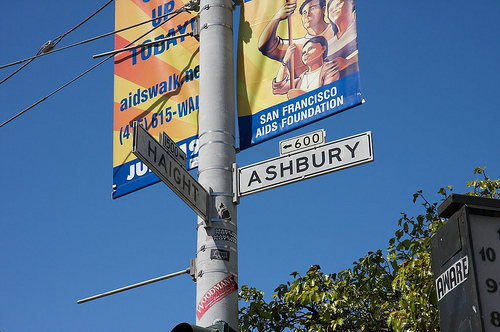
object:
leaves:
[322, 271, 359, 308]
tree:
[235, 169, 438, 332]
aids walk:
[107, 0, 361, 195]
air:
[4, 4, 114, 205]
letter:
[246, 169, 261, 185]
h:
[278, 159, 293, 177]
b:
[294, 155, 310, 173]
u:
[312, 151, 325, 168]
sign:
[312, 151, 326, 168]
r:
[327, 146, 342, 162]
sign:
[328, 147, 344, 164]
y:
[342, 138, 362, 158]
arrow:
[283, 143, 292, 149]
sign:
[230, 121, 377, 193]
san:
[258, 108, 279, 124]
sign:
[99, 1, 371, 204]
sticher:
[193, 270, 245, 322]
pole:
[188, 1, 244, 332]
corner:
[417, 183, 499, 330]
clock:
[468, 204, 500, 331]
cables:
[1, 2, 200, 131]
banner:
[102, 1, 369, 210]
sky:
[5, 0, 492, 233]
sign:
[128, 117, 215, 217]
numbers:
[161, 131, 180, 158]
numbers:
[293, 132, 319, 149]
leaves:
[392, 279, 431, 312]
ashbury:
[238, 130, 371, 194]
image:
[261, 0, 355, 100]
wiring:
[4, 3, 193, 137]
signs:
[234, 129, 375, 198]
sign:
[192, 230, 245, 330]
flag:
[106, 1, 370, 223]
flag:
[129, 117, 214, 220]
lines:
[1, 0, 194, 125]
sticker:
[436, 254, 471, 304]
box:
[428, 196, 500, 332]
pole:
[70, 267, 192, 305]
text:
[249, 83, 347, 140]